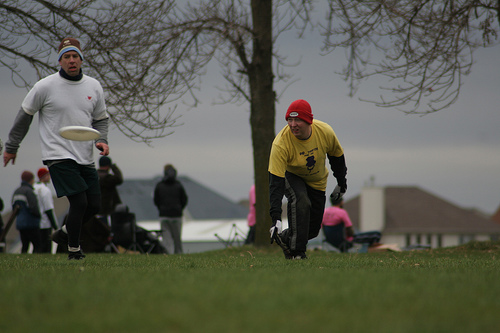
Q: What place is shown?
A: It is a field.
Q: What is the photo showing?
A: It is showing a field.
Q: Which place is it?
A: It is a field.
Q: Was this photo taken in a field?
A: Yes, it was taken in a field.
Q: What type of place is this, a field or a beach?
A: It is a field.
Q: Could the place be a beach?
A: No, it is a field.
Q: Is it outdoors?
A: Yes, it is outdoors.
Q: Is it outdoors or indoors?
A: It is outdoors.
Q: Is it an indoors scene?
A: No, it is outdoors.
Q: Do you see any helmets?
A: No, there are no helmets.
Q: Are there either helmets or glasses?
A: No, there are no helmets or glasses.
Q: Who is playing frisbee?
A: The man is playing frisbee.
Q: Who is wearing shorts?
A: The man is wearing shorts.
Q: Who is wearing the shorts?
A: The man is wearing shorts.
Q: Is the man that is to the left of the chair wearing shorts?
A: Yes, the man is wearing shorts.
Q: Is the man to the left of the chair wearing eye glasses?
A: No, the man is wearing shorts.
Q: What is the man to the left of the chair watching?
A: The man is watching the frisbee.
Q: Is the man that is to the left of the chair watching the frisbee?
A: Yes, the man is watching the frisbee.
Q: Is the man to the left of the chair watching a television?
A: No, the man is watching the frisbee.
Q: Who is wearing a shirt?
A: The man is wearing a shirt.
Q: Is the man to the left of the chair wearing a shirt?
A: Yes, the man is wearing a shirt.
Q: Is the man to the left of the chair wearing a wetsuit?
A: No, the man is wearing a shirt.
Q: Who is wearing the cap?
A: The man is wearing a cap.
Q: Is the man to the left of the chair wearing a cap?
A: Yes, the man is wearing a cap.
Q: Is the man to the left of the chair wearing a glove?
A: No, the man is wearing a cap.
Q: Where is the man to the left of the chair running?
A: The man is running on the field.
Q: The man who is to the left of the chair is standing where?
A: The man is standing on the field.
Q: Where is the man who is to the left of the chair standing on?
A: The man is standing on the field.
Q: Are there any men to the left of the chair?
A: Yes, there is a man to the left of the chair.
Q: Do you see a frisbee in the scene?
A: Yes, there is a frisbee.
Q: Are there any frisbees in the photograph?
A: Yes, there is a frisbee.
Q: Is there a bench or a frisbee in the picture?
A: Yes, there is a frisbee.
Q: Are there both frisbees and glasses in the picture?
A: No, there is a frisbee but no glasses.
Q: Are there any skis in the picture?
A: No, there are no skis.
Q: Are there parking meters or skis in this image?
A: No, there are no skis or parking meters.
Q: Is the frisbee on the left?
A: Yes, the frisbee is on the left of the image.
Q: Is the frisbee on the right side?
A: No, the frisbee is on the left of the image.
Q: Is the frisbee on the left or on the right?
A: The frisbee is on the left of the image.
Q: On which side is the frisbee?
A: The frisbee is on the left of the image.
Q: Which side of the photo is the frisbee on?
A: The frisbee is on the left of the image.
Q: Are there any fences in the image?
A: No, there are no fences.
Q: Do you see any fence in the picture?
A: No, there are no fences.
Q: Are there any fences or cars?
A: No, there are no fences or cars.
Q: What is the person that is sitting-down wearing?
A: The person is wearing a shirt.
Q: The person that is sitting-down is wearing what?
A: The person is wearing a shirt.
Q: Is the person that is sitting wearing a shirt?
A: Yes, the person is wearing a shirt.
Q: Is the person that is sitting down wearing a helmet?
A: No, the person is wearing a shirt.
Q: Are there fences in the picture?
A: No, there are no fences.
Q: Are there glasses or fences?
A: No, there are no fences or glasses.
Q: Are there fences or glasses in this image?
A: No, there are no fences or glasses.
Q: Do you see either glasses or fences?
A: No, there are no fences or glasses.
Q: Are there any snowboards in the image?
A: No, there are no snowboards.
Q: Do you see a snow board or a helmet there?
A: No, there are no snowboards or helmets.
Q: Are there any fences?
A: No, there are no fences.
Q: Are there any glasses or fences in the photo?
A: No, there are no fences or glasses.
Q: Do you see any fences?
A: No, there are no fences.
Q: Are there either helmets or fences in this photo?
A: No, there are no fences or helmets.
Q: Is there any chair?
A: Yes, there is a chair.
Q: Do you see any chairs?
A: Yes, there is a chair.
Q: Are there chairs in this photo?
A: Yes, there is a chair.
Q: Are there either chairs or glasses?
A: Yes, there is a chair.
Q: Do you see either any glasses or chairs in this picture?
A: Yes, there is a chair.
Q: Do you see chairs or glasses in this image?
A: Yes, there is a chair.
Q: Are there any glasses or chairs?
A: Yes, there is a chair.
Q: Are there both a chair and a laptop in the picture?
A: No, there is a chair but no laptops.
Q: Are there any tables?
A: No, there are no tables.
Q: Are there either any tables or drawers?
A: No, there are no tables or drawers.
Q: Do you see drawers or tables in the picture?
A: No, there are no tables or drawers.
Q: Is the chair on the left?
A: Yes, the chair is on the left of the image.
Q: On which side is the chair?
A: The chair is on the left of the image.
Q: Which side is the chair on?
A: The chair is on the left of the image.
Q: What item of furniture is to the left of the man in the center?
A: The piece of furniture is a chair.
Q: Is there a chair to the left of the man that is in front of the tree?
A: Yes, there is a chair to the left of the man.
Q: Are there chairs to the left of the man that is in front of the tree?
A: Yes, there is a chair to the left of the man.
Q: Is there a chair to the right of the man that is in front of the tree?
A: No, the chair is to the left of the man.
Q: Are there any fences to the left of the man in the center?
A: No, there is a chair to the left of the man.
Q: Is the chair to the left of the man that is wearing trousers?
A: Yes, the chair is to the left of the man.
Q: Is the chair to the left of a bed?
A: No, the chair is to the left of the man.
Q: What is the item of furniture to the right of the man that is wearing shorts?
A: The piece of furniture is a chair.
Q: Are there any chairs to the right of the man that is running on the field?
A: Yes, there is a chair to the right of the man.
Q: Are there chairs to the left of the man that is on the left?
A: No, the chair is to the right of the man.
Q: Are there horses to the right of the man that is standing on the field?
A: No, there is a chair to the right of the man.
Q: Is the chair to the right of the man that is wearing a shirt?
A: Yes, the chair is to the right of the man.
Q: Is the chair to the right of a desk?
A: No, the chair is to the right of the man.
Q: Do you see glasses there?
A: No, there are no glasses.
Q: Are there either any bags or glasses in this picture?
A: No, there are no glasses or bags.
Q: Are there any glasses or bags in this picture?
A: No, there are no glasses or bags.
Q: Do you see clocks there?
A: No, there are no clocks.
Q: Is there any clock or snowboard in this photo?
A: No, there are no clocks or snowboards.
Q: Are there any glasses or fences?
A: No, there are no fences or glasses.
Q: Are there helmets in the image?
A: No, there are no helmets.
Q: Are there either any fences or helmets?
A: No, there are no helmets or fences.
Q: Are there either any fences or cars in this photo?
A: No, there are no fences or cars.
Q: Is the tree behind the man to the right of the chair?
A: Yes, the tree is behind the man.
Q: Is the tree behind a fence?
A: No, the tree is behind the man.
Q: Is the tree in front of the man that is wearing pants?
A: No, the tree is behind the man.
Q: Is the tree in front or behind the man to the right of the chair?
A: The tree is behind the man.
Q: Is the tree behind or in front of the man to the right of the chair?
A: The tree is behind the man.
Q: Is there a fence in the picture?
A: No, there are no fences.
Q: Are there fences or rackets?
A: No, there are no fences or rackets.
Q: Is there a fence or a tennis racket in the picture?
A: No, there are no fences or rackets.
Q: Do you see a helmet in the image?
A: No, there are no helmets.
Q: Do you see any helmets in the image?
A: No, there are no helmets.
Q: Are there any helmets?
A: No, there are no helmets.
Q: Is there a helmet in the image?
A: No, there are no helmets.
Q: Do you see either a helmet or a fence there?
A: No, there are no helmets or fences.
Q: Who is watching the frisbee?
A: The man is watching the frisbee.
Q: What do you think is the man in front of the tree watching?
A: The man is watching the frisbee.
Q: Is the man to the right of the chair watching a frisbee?
A: Yes, the man is watching a frisbee.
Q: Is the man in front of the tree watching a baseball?
A: No, the man is watching a frisbee.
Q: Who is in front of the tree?
A: The man is in front of the tree.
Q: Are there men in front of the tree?
A: Yes, there is a man in front of the tree.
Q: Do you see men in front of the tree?
A: Yes, there is a man in front of the tree.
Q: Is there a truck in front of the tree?
A: No, there is a man in front of the tree.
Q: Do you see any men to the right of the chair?
A: Yes, there is a man to the right of the chair.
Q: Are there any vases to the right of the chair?
A: No, there is a man to the right of the chair.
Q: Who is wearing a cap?
A: The man is wearing a cap.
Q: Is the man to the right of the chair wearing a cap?
A: Yes, the man is wearing a cap.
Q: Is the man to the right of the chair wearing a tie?
A: No, the man is wearing a cap.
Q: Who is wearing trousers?
A: The man is wearing trousers.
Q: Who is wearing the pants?
A: The man is wearing trousers.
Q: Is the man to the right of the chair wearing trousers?
A: Yes, the man is wearing trousers.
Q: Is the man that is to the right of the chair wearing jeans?
A: No, the man is wearing trousers.